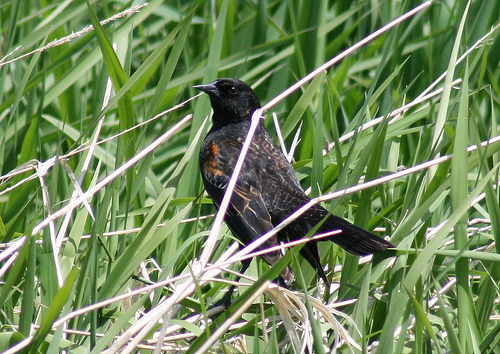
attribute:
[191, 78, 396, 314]
bird — black, small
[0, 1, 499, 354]
grass — green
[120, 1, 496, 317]
branches — dry, gray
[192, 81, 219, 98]
beak — black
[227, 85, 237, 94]
eyes — open, black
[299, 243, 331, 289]
feather — black